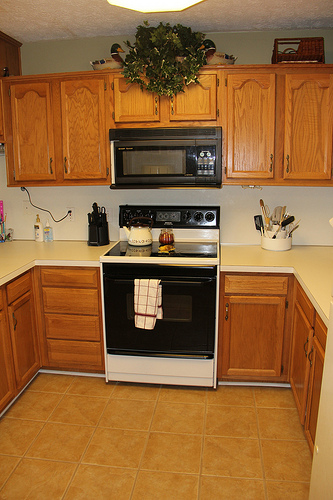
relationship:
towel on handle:
[132, 278, 165, 333] [113, 278, 212, 285]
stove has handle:
[99, 200, 219, 380] [113, 278, 212, 285]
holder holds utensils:
[258, 222, 290, 251] [253, 200, 299, 238]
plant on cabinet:
[120, 24, 208, 99] [0, 65, 332, 187]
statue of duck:
[199, 39, 237, 65] [197, 39, 237, 63]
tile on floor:
[0, 370, 311, 497] [2, 374, 311, 499]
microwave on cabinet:
[108, 125, 224, 190] [0, 65, 332, 187]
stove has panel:
[99, 204, 219, 264] [117, 205, 218, 231]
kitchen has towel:
[2, 2, 331, 497] [132, 278, 165, 333]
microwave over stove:
[108, 125, 224, 190] [99, 204, 219, 264]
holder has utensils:
[258, 222, 290, 251] [253, 200, 299, 238]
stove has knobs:
[99, 204, 219, 264] [117, 206, 219, 226]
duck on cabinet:
[197, 39, 237, 63] [0, 65, 332, 187]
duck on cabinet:
[88, 43, 130, 69] [0, 65, 332, 187]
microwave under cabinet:
[108, 125, 224, 190] [0, 65, 332, 187]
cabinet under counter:
[2, 265, 331, 455] [0, 238, 330, 324]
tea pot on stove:
[122, 218, 153, 247] [99, 204, 219, 264]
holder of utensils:
[258, 222, 290, 251] [253, 200, 299, 238]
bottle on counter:
[33, 213, 43, 240] [0, 238, 330, 324]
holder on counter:
[258, 222, 290, 251] [0, 238, 330, 324]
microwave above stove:
[108, 125, 224, 190] [99, 204, 219, 264]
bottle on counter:
[43, 222, 51, 241] [0, 238, 330, 324]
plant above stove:
[120, 24, 208, 99] [99, 204, 219, 264]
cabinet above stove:
[0, 65, 332, 187] [99, 204, 219, 264]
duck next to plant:
[197, 39, 237, 63] [120, 24, 208, 99]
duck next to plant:
[88, 43, 130, 69] [120, 24, 208, 99]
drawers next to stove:
[41, 269, 102, 377] [99, 204, 219, 264]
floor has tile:
[2, 374, 311, 499] [0, 370, 311, 497]